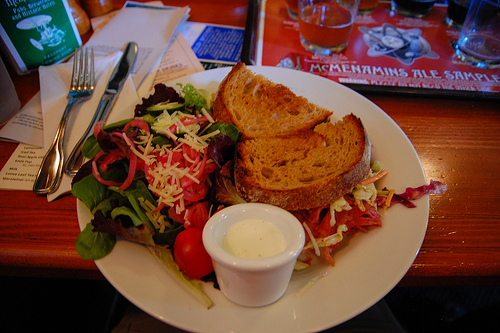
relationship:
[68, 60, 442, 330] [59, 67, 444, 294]
plate full of food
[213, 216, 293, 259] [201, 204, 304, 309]
salad dressing in dish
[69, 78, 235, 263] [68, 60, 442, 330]
salad on plate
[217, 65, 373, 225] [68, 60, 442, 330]
sandwich on plate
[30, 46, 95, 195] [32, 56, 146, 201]
fork on napkin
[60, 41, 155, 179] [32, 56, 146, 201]
knife on napkin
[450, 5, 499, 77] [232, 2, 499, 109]
glass sitting on tray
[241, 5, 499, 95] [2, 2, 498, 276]
tray on table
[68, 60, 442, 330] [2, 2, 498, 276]
plate on table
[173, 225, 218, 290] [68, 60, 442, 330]
cherry tomato on plate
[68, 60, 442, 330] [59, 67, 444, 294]
plate of food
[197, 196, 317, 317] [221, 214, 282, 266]
container with salad dressing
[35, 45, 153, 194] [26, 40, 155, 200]
silverware on top of a napkin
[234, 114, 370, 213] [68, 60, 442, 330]
bread on plate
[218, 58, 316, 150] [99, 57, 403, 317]
toast on plate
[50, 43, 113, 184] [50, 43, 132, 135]
fork on napkin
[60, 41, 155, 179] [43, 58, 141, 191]
knife on napkin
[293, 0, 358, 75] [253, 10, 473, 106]
bear on sample menu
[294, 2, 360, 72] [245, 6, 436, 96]
beer on sample menu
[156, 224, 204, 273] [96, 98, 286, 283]
tomato in salad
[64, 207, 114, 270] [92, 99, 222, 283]
lettuce in salad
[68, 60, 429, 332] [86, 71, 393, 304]
plate full of food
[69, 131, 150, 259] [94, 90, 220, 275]
salad with vegetable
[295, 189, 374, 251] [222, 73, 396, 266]
meat and sandwich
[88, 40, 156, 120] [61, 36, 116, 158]
knife and fork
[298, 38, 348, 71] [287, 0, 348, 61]
bottom of a glass